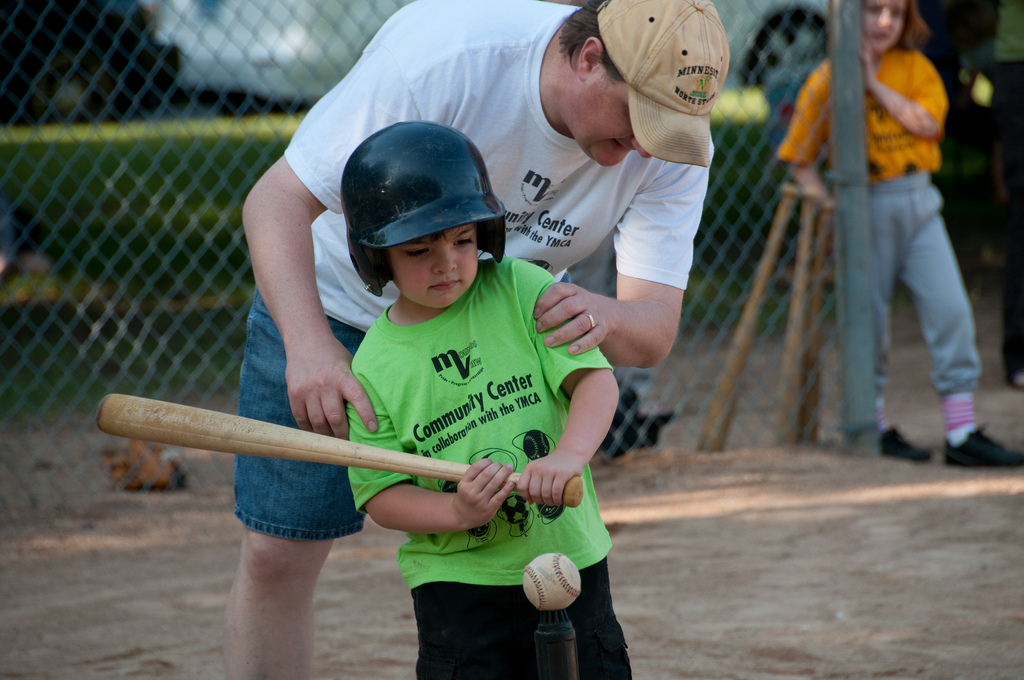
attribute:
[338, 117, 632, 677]
boy — little